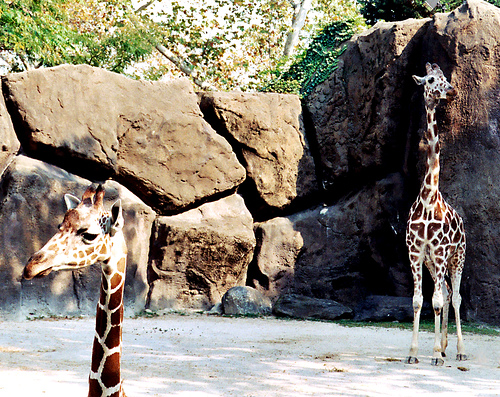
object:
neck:
[89, 259, 128, 397]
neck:
[422, 103, 440, 191]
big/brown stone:
[197, 90, 319, 210]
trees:
[0, 0, 372, 94]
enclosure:
[0, 0, 500, 397]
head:
[21, 185, 125, 284]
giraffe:
[19, 181, 126, 397]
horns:
[94, 182, 105, 208]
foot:
[431, 357, 445, 365]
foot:
[455, 354, 468, 361]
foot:
[404, 356, 419, 364]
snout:
[445, 87, 457, 95]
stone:
[248, 169, 406, 296]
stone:
[0, 63, 246, 208]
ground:
[0, 313, 500, 396]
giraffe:
[403, 62, 467, 368]